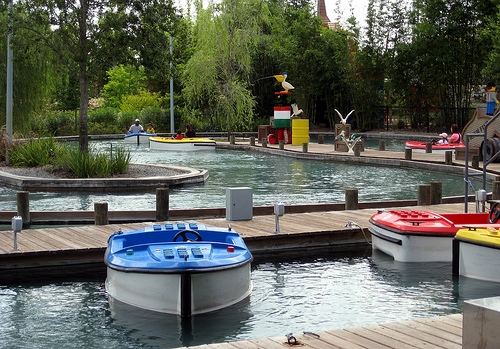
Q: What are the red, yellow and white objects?
A: Boats.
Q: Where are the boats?
A: Dock.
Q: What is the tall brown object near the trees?
A: Chimney.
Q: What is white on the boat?
A: Hull.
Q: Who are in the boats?
A: Riders.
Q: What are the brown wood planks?
A: Dock.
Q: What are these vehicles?
A: Amusement park boats.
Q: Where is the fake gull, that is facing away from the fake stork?
A: On the edge of a yellow barrel.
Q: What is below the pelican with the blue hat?
A: A perc, and a red, white and green barrel.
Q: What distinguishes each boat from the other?
A: The colorful top portions.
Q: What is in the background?
A: Trees.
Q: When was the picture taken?
A: Daytime.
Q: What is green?
A: The trees.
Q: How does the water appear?
A: Calm.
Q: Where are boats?
A: In the water.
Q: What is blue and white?
A: Boat on left.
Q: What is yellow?
A: Boat on right.